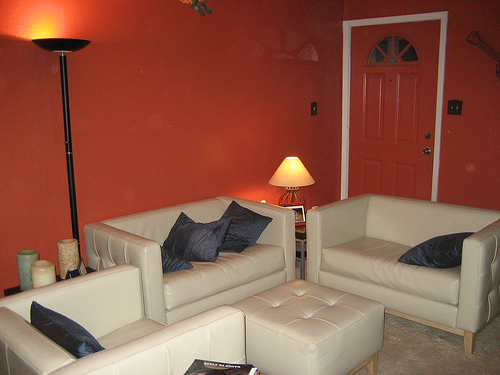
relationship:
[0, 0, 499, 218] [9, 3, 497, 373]
red wall in room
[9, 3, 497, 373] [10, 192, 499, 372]
room with furniture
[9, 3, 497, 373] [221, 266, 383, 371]
room with ottoman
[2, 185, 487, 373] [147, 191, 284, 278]
couches have pillows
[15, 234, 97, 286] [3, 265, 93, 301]
candles on top of table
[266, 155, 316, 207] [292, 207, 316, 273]
lamp on top of table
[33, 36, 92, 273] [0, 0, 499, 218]
floor lamp next to red wall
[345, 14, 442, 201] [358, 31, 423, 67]
red door has insert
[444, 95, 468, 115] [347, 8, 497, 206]
switch on wall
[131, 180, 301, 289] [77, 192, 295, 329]
pillows on couch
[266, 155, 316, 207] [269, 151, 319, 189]
lamp with a white shade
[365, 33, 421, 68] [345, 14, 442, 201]
window on a red door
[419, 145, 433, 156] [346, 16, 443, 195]
door knob on a door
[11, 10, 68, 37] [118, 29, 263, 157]
light glare on red wall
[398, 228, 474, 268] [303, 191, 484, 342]
pillow on couch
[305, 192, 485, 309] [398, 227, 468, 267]
couch with a blue pillow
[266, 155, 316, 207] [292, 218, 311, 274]
lamp on table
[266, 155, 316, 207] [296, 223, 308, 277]
lamp on table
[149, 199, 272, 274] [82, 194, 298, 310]
blue pillows on couch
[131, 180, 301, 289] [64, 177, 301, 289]
pillows on sofa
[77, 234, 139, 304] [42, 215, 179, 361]
candles on table